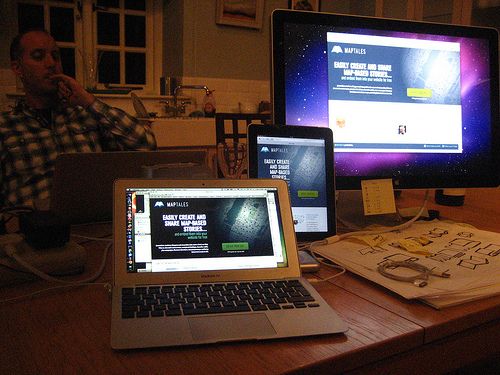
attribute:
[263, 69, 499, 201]
computer — black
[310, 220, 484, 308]
white paper — stack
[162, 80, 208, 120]
sink — silver, large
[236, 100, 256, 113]
tea pot — white, ceramic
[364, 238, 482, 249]
paper — folded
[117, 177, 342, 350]
laptop — open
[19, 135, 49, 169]
shirt — checkered 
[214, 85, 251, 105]
backsplash — white, stone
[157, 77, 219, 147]
kitchen sink — large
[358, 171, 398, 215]
note — small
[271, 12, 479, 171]
monitor — large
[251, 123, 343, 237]
ipad — propped